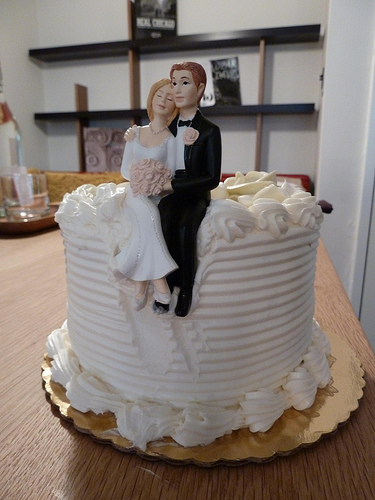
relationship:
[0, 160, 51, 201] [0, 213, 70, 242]
glass on tray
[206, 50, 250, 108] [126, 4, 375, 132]
book on shelf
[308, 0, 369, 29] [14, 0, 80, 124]
corner in left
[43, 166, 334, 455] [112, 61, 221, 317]
cake have doll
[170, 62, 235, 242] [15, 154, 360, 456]
man topping cake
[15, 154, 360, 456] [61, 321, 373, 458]
cake on plate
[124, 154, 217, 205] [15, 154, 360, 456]
bouquet on cake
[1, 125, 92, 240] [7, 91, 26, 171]
glasses by bottle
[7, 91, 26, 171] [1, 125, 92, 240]
bottle near glasses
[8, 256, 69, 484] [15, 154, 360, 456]
table under cake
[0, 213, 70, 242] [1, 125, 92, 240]
tray holding glasses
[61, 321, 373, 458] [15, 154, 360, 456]
frosting below cake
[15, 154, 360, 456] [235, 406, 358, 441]
cake on stand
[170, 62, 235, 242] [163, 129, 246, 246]
man in tuxedo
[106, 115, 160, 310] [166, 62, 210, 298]
bride and groom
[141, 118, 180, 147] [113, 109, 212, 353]
necklace on doll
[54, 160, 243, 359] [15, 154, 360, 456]
frosting on cake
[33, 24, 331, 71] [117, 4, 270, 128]
shelves have books